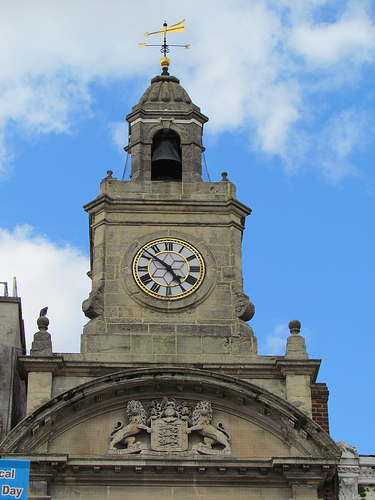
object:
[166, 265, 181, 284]
hand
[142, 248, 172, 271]
hand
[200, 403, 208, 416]
face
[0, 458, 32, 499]
blue sign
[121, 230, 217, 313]
clock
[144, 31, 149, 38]
arrow heads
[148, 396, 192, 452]
statue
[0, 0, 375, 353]
clouds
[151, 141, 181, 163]
bell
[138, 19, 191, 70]
wind meter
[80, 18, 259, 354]
stone clock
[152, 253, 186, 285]
star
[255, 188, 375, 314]
blue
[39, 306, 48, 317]
bird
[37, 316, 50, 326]
top stone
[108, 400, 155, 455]
carvings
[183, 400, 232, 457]
carvings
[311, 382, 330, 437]
brick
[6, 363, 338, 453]
structure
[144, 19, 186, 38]
vane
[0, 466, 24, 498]
cal day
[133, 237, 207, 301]
4:53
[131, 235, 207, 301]
golden trim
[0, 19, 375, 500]
architecture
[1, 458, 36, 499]
corner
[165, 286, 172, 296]
numbers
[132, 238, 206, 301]
face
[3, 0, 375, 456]
sky